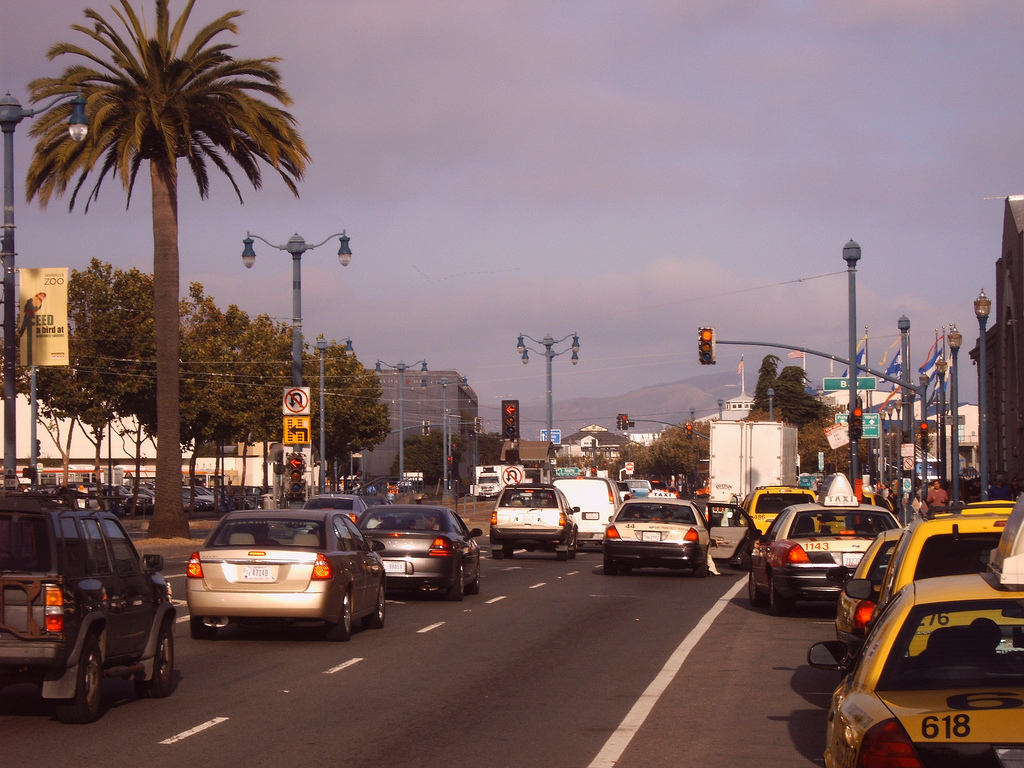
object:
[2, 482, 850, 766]
road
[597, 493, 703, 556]
vehicle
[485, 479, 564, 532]
vehicle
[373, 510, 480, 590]
vehicle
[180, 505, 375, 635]
vehicle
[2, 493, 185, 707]
vehicle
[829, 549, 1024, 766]
taxi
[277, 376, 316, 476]
signs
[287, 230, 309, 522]
pole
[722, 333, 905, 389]
pole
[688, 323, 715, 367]
light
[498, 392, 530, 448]
light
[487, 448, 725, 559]
vehicles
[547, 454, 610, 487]
sign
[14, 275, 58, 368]
bird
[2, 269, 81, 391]
sign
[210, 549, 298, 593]
license plate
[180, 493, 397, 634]
car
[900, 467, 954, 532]
person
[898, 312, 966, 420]
flags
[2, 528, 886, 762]
road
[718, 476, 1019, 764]
taxi cabs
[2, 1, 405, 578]
palm trees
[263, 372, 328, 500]
street signs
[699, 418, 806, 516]
truck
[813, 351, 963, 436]
flags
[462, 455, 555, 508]
truck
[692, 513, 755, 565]
door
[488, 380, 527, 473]
street light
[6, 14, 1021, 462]
clouds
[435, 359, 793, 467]
mountain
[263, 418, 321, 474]
sign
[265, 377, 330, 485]
sign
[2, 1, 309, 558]
palm tree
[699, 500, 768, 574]
door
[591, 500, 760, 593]
taxi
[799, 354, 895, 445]
street sign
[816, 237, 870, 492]
poles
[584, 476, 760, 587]
taxi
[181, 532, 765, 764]
lane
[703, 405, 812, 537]
semi truck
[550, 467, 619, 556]
van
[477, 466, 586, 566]
suv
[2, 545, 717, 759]
lane road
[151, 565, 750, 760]
lines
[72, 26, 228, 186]
tree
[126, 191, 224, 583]
trunk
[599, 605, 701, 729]
line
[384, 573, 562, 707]
road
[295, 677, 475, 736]
road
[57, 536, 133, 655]
car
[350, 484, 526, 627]
car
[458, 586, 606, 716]
road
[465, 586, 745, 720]
road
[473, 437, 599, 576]
car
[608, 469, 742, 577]
car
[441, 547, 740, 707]
road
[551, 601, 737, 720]
road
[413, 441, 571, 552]
car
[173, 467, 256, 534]
car